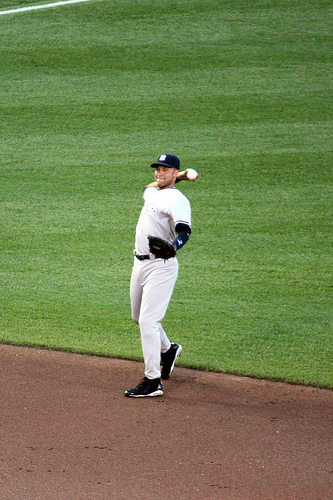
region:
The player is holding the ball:
[117, 145, 202, 403]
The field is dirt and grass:
[5, 0, 328, 493]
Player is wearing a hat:
[147, 151, 182, 189]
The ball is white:
[183, 167, 200, 184]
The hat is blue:
[149, 150, 180, 187]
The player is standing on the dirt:
[119, 144, 200, 400]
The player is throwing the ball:
[118, 145, 198, 399]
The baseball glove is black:
[146, 234, 179, 263]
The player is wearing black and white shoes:
[123, 340, 184, 400]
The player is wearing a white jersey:
[131, 148, 202, 256]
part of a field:
[230, 88, 253, 107]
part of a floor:
[218, 412, 232, 452]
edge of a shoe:
[126, 387, 157, 419]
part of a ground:
[224, 447, 248, 472]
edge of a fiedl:
[277, 380, 311, 412]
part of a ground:
[210, 441, 233, 470]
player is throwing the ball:
[121, 149, 204, 405]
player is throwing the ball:
[133, 147, 221, 305]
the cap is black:
[147, 147, 199, 179]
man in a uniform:
[96, 145, 232, 397]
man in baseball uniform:
[74, 140, 207, 409]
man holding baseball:
[121, 147, 205, 405]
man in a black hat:
[18, 149, 224, 401]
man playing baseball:
[102, 145, 241, 425]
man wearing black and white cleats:
[94, 151, 216, 398]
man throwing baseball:
[102, 145, 221, 405]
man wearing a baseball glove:
[110, 147, 218, 410]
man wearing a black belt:
[104, 103, 194, 401]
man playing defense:
[86, 148, 234, 396]